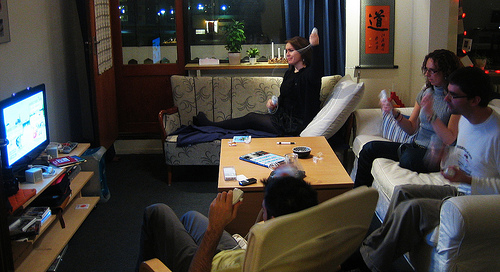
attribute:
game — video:
[1, 77, 52, 180]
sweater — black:
[261, 66, 324, 139]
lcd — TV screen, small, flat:
[0, 69, 69, 166]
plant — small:
[242, 39, 266, 65]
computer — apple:
[3, 65, 88, 190]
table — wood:
[194, 121, 343, 210]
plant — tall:
[214, 11, 254, 63]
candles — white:
[263, 35, 285, 65]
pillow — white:
[367, 109, 417, 140]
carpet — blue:
[103, 138, 159, 267]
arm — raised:
[306, 17, 335, 53]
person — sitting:
[413, 48, 497, 215]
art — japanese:
[355, 0, 400, 78]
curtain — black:
[262, 4, 364, 92]